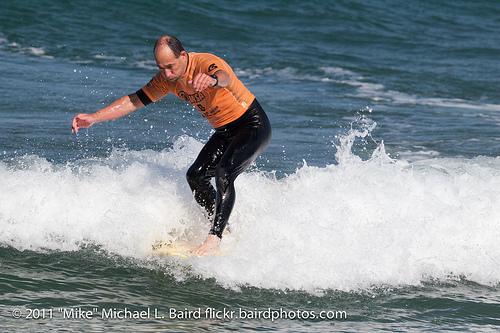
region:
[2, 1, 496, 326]
A surfer in the ocean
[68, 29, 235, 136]
Surfer has two arms raised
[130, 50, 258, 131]
A yellow and wet shirt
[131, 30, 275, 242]
Man is wearing a black wetsuit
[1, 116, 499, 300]
A large wave in the ocean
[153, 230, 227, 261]
Feet on a surfboard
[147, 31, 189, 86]
The surfer has brown hair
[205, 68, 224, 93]
A black watch around a wrist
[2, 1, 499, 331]
The ocean appears rough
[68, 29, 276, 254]
The surfer is all wet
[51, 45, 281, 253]
this is a man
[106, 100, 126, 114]
the man is light skinned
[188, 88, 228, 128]
this is a t shirt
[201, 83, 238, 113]
the t shirt is orange in color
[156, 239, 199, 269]
this is a surfboard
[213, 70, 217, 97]
this is a wrist watch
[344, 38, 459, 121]
this is a water body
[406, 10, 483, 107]
the water is calm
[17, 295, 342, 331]
this is a writing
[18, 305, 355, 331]
the writing is in white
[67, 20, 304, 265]
A man is in the foreground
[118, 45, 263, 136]
Man is wearing a orange shirt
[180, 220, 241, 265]
Man in the foreground is barefoot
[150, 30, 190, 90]
Man's hair is dark colored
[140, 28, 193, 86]
Man surfing hair is balding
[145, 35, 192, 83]
Man is looking down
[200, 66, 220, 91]
Man is wearing a wrist watch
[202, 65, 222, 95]
Wrist watch is black in color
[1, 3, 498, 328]
Photo was taken outdoors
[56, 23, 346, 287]
a surfer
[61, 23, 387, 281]
a man is surfing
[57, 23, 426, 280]
a man is balancing on a surfboard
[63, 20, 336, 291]
the surfer wears an orange shirt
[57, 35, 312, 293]
the surfer wears black wet suit pants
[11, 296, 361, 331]
a description is written at the bottom of the photo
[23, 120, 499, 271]
the wave is small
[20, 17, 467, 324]
the man surfs in the ocean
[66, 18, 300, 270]
the man holds his arms out for balance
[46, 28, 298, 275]
the man is looking down at the water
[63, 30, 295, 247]
surfer riding a wave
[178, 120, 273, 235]
black wetshit pants of man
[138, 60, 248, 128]
orange shirt of man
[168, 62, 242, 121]
black text on orange shirt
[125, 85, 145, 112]
shadow on man's arm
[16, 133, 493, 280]
white foam of crashing wave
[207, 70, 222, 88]
black wristwatch of man surfing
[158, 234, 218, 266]
surfboard man is standing on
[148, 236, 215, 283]
white surfboard on ocean water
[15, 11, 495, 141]
waters behind the wave